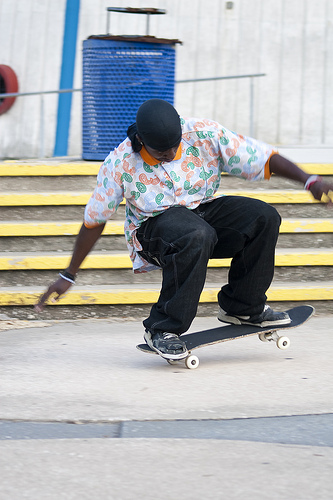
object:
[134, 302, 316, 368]
board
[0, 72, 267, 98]
railing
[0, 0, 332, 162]
building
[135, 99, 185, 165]
head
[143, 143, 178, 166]
face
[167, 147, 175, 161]
nose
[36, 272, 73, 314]
hand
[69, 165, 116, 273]
arm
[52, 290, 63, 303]
fingers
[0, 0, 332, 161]
wall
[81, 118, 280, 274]
shirt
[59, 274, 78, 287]
bracelet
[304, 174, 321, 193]
bracelet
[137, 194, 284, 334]
jeans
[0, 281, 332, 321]
steps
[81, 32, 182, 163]
trash can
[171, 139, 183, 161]
collar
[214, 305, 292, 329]
shoe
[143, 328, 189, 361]
shoe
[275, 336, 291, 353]
wheel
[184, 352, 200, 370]
wheel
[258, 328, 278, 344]
wheel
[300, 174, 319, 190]
bracelet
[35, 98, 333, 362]
guy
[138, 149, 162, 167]
collar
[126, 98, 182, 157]
durag